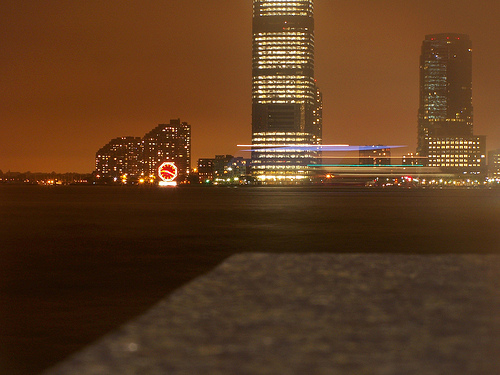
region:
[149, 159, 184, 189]
circular neon clock in the city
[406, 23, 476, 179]
tall lit up building with red lights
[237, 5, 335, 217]
tall lit up building in the city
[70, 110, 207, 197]
group of lit up buildings in the city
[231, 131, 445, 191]
lights streaking in the night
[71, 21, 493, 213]
lit up city skyline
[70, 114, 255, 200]
buildings lit up at night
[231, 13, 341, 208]
tall buildings with lit up windows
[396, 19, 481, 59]
red lights at the top of the building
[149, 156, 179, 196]
neon clock reading 9:20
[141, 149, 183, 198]
a large neon clock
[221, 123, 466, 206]
lights streaking the sky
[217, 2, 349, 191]
a tall building with lights on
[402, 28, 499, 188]
a tall bill in the background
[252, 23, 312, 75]
lights on the building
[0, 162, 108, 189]
trees behind the buildings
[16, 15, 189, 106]
a burnt orange sky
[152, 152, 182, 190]
a light up clock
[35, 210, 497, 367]
concrete slab next to the water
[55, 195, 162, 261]
dark water in front of the buildings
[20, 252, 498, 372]
a square, manmade body of water. which type i do not know, although i'm pretty sure it's on a roof. so: swimming pool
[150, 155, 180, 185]
a monumentally sized bright red neon clock w/ white numbers, hands & unintelligible logo beneath, reading, oh, about 9:20pm, say.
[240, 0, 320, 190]
a whopping skyscraper, so tall it makes the skyscrapers beside+behind it look nearly miniaturized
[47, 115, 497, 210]
this is time lapse photography, that's why you have the green+purple+yellow lines across. but some of the time lapse doesnt make sense, so i'm assuming the time was something like a minute. anyway.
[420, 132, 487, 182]
a small skyscraper, mid-right, with many lit square windows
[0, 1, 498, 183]
a reddish brown sky, brightened+coloured by all the skyscraper+business district lights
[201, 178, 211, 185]
a single green traffic light, at left-middle, near bottom of the street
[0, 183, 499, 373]
what i think is probably concrete, darkly painted, surrounding the angled pool on the roof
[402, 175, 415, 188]
one red traffic light, at mid-right, close to the bottom of the street as per the green one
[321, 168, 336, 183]
a yellow traffic light, can it be, approx equidistant between the red+the green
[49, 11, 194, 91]
The sky is brown.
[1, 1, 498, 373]
The picture is taken at night.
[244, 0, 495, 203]
The buildings are tall.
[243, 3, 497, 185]
The lights are on.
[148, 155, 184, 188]
A clock is lite up.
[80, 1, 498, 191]
The lights are bright.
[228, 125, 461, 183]
The lights are making streaks.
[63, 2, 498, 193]
A city sky line.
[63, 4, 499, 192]
The buildings have lights in them.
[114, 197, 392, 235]
Water is in the picture.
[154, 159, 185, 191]
Lit up neon clock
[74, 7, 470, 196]
Cityscape at night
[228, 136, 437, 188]
Blurred colors in the picture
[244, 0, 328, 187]
Skyscraper across the water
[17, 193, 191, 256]
Dark water of a river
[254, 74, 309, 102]
Lights on in the building across the water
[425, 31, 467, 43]
Red lights on the top of a building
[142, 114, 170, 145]
Edge of building that looks like stairs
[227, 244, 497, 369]
Marble slab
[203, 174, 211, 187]
Green light on building across the river